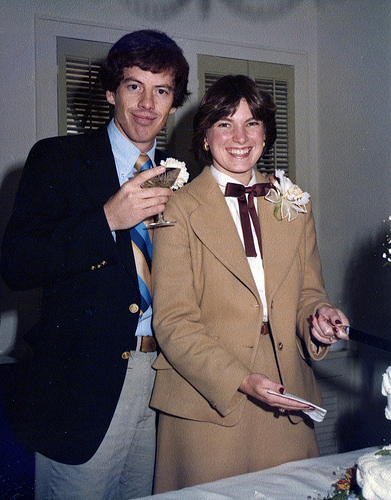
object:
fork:
[324, 320, 391, 356]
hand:
[309, 305, 351, 345]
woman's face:
[206, 98, 267, 172]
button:
[129, 303, 139, 313]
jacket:
[4, 128, 170, 465]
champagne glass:
[133, 168, 181, 227]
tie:
[129, 153, 155, 319]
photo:
[0, 0, 389, 499]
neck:
[213, 161, 252, 186]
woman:
[146, 73, 352, 500]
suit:
[3, 124, 180, 497]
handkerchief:
[266, 389, 328, 424]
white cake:
[356, 365, 391, 500]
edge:
[357, 456, 374, 497]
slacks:
[34, 334, 157, 500]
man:
[0, 29, 193, 500]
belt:
[130, 335, 157, 353]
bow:
[225, 181, 278, 257]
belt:
[261, 323, 270, 335]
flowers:
[305, 465, 362, 500]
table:
[115, 440, 389, 499]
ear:
[203, 132, 209, 151]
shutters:
[65, 58, 166, 148]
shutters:
[204, 72, 289, 180]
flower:
[264, 168, 312, 224]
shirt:
[211, 164, 269, 321]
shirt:
[107, 116, 155, 336]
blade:
[346, 326, 391, 352]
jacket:
[148, 163, 333, 426]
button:
[211, 399, 218, 407]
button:
[278, 342, 283, 351]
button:
[271, 300, 273, 309]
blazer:
[0, 121, 141, 467]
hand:
[110, 165, 171, 231]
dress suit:
[147, 164, 334, 499]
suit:
[150, 166, 334, 494]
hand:
[239, 373, 316, 413]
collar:
[187, 166, 275, 202]